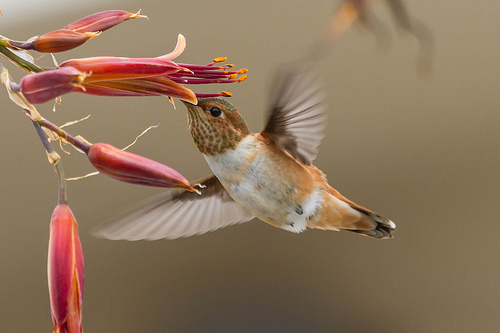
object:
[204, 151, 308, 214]
bird's fur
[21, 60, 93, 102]
flower petals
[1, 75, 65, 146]
flowers stem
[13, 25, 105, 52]
pink flowers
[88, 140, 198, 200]
red/orange flower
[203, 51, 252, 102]
flower top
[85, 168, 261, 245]
bird wings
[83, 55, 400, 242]
bird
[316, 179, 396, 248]
birds tail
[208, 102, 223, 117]
bird's eye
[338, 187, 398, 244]
feathers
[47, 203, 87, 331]
flower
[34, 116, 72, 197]
stem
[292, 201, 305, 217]
feet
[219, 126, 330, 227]
body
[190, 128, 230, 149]
chin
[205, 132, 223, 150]
spots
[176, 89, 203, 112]
beak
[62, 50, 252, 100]
flower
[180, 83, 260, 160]
head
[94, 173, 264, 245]
wing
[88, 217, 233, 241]
tips